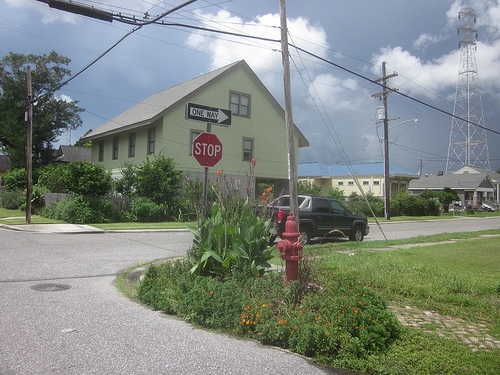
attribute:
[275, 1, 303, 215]
pole — pictured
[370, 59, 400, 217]
pole — pictured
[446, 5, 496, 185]
pylon — electric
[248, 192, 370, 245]
car — black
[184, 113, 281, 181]
stop sign —  stop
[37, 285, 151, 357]
road — tarmac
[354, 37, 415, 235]
power pole — for Power 